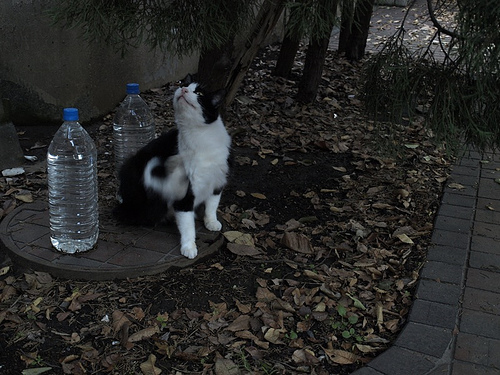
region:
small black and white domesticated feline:
[113, 70, 244, 262]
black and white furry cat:
[107, 63, 239, 261]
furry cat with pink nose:
[112, 79, 253, 267]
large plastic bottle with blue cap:
[39, 101, 114, 263]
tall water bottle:
[37, 105, 113, 265]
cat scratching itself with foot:
[113, 70, 249, 267]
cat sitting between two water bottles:
[47, 63, 242, 274]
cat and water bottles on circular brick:
[38, 59, 259, 276]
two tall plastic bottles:
[37, 70, 164, 268]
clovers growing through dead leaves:
[325, 299, 371, 350]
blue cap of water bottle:
[52, 100, 84, 122]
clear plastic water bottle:
[42, 122, 106, 252]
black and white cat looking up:
[118, 72, 233, 258]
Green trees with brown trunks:
[57, 7, 382, 60]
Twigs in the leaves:
[241, 240, 328, 271]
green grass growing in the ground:
[329, 299, 366, 349]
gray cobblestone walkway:
[358, 142, 498, 374]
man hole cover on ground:
[11, 197, 222, 288]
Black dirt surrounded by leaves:
[232, 147, 359, 218]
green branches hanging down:
[357, 17, 495, 165]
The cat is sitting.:
[97, 70, 273, 263]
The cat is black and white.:
[106, 64, 278, 276]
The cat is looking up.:
[158, 67, 240, 132]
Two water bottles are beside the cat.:
[35, 70, 159, 259]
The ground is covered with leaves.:
[199, 212, 418, 373]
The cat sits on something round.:
[0, 65, 257, 289]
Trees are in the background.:
[41, 0, 495, 118]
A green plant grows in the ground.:
[277, 296, 372, 351]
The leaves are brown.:
[218, 201, 415, 303]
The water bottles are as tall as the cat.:
[31, 64, 239, 266]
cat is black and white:
[110, 73, 249, 253]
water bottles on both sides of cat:
[21, 54, 211, 244]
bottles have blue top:
[33, 28, 167, 123]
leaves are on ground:
[10, 51, 482, 373]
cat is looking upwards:
[150, 56, 249, 140]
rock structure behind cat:
[2, 0, 259, 113]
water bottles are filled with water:
[16, 31, 186, 241]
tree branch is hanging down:
[375, 6, 492, 133]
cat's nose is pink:
[176, 82, 193, 102]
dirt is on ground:
[225, 131, 393, 238]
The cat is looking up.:
[154, 67, 251, 128]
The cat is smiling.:
[162, 70, 224, 115]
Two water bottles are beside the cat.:
[29, 73, 159, 263]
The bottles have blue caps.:
[53, 78, 143, 127]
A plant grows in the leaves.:
[315, 295, 367, 347]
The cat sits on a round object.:
[5, 67, 250, 282]